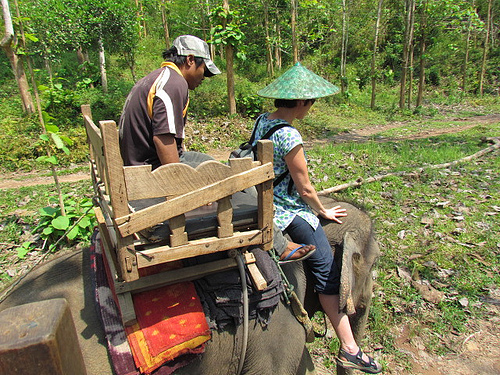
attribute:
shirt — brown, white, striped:
[113, 60, 189, 163]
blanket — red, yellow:
[98, 240, 213, 373]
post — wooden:
[5, 291, 73, 371]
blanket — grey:
[195, 245, 282, 330]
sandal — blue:
[281, 242, 318, 264]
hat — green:
[244, 64, 330, 93]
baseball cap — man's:
[171, 33, 221, 77]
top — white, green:
[251, 110, 323, 235]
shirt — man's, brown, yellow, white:
[116, 67, 196, 157]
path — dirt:
[8, 119, 479, 200]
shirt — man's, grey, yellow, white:
[118, 60, 190, 158]